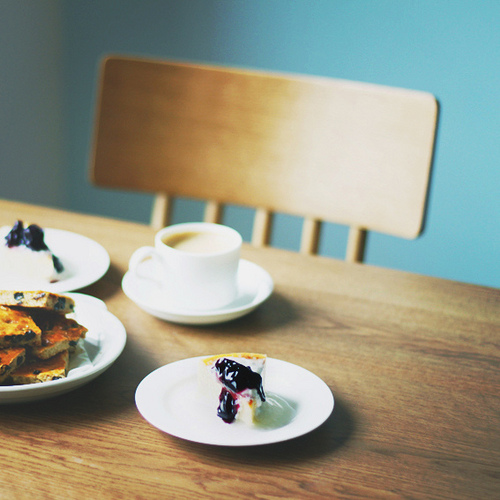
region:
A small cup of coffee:
[126, 220, 243, 304]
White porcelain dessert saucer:
[135, 352, 337, 449]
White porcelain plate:
[0, 290, 128, 406]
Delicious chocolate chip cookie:
[0, 288, 75, 318]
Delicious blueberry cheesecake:
[203, 350, 273, 427]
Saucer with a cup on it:
[119, 215, 276, 327]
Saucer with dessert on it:
[133, 347, 336, 445]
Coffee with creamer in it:
[163, 228, 240, 252]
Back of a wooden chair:
[88, 57, 435, 205]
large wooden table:
[0, 195, 497, 496]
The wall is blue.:
[23, 22, 260, 66]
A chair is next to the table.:
[110, 69, 433, 205]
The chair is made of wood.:
[83, 81, 344, 186]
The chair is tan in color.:
[126, 72, 386, 220]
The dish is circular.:
[163, 351, 349, 468]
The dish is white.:
[148, 349, 333, 476]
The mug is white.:
[118, 205, 256, 319]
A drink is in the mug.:
[163, 218, 255, 295]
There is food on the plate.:
[176, 355, 314, 445]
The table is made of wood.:
[363, 296, 441, 465]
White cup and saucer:
[103, 207, 303, 337]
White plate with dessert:
[122, 329, 373, 456]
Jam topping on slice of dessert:
[198, 352, 275, 441]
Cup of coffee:
[111, 197, 304, 336]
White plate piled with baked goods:
[1, 260, 138, 397]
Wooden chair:
[35, 52, 467, 255]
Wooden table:
[0, 196, 499, 492]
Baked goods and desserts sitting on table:
[0, 168, 496, 495]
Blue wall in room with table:
[52, 21, 499, 283]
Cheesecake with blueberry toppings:
[116, 320, 366, 472]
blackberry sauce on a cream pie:
[226, 357, 253, 387]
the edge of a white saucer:
[171, 307, 245, 323]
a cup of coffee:
[140, 220, 251, 300]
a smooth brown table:
[386, 306, 463, 391]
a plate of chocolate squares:
[7, 287, 79, 364]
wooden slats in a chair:
[262, 217, 358, 248]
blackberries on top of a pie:
[24, 221, 38, 252]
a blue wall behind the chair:
[400, 38, 477, 84]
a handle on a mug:
[135, 245, 157, 284]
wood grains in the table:
[386, 365, 464, 448]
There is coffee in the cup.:
[130, 216, 280, 336]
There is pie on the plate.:
[155, 349, 332, 454]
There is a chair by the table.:
[95, 37, 441, 280]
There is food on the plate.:
[0, 274, 141, 417]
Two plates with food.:
[0, 298, 361, 486]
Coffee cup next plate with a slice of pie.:
[135, 218, 350, 465]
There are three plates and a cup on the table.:
[0, 211, 363, 478]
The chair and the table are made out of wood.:
[73, 21, 471, 496]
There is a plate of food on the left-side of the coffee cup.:
[10, 202, 274, 317]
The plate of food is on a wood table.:
[129, 332, 353, 479]